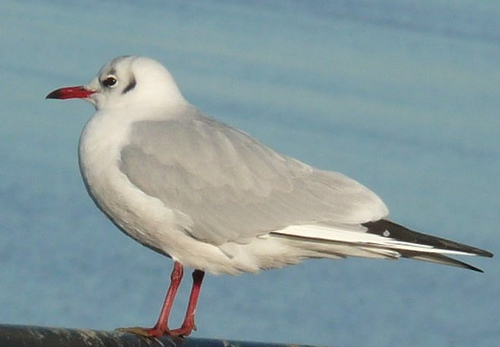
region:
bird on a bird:
[21, 38, 481, 337]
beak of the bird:
[53, 78, 84, 107]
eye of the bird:
[108, 76, 120, 96]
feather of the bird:
[171, 160, 212, 205]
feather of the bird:
[232, 204, 267, 229]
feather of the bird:
[280, 200, 315, 219]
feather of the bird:
[340, 227, 387, 248]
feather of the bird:
[211, 249, 233, 269]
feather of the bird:
[133, 220, 169, 257]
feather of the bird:
[290, 231, 345, 260]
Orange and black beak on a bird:
[38, 78, 103, 110]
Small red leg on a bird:
[115, 244, 183, 344]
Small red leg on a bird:
[179, 261, 206, 344]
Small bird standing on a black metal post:
[18, 50, 451, 346]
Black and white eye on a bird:
[100, 66, 124, 93]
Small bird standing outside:
[40, 43, 483, 344]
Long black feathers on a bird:
[367, 207, 493, 269]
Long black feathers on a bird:
[395, 248, 485, 287]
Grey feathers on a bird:
[119, 109, 378, 229]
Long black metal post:
[4, 318, 179, 345]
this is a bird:
[33, 42, 490, 340]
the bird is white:
[84, 74, 397, 284]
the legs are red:
[136, 242, 208, 340]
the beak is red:
[21, 48, 86, 115]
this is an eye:
[98, 65, 123, 111]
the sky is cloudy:
[281, 103, 371, 168]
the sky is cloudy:
[227, 65, 318, 111]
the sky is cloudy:
[364, 29, 441, 134]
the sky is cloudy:
[6, 236, 87, 303]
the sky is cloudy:
[244, 65, 381, 139]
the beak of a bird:
[33, 62, 93, 114]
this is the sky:
[338, 47, 403, 122]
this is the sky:
[14, 90, 78, 196]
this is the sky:
[228, 47, 309, 120]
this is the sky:
[385, 105, 445, 188]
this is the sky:
[35, 153, 80, 273]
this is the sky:
[203, 30, 288, 95]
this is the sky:
[341, 129, 448, 194]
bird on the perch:
[15, 32, 492, 339]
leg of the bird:
[183, 264, 206, 342]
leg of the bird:
[134, 258, 176, 340]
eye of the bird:
[98, 68, 120, 95]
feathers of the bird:
[188, 143, 228, 181]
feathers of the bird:
[236, 180, 271, 215]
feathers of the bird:
[284, 194, 319, 220]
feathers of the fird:
[337, 218, 403, 248]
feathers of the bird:
[218, 236, 262, 268]